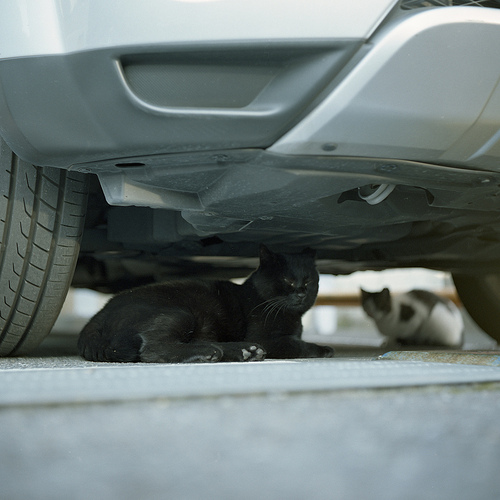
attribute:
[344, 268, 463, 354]
cat — white, brown, sitting down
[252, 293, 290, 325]
whiskers — white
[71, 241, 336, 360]
cat — black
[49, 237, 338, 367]
cat — black, sitting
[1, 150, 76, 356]
tire — car tire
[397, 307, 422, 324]
spots — dark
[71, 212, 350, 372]
cat — black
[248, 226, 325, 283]
ears — black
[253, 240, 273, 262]
ear — dark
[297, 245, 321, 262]
ear — dark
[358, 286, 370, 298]
ear — dark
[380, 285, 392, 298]
ear — dark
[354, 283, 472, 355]
cat — brown, white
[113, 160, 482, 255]
undercarriage — grey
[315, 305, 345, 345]
bucket — white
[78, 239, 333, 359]
black cat — sitting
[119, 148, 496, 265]
bottom — bottom part of car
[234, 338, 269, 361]
paw — cat's paw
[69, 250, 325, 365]
cat — black, under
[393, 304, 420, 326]
spots — grey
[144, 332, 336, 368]
legs — hind legs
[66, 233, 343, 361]
cat — black cat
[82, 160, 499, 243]
underside — of a car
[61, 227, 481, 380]
cats — under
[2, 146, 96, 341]
wheel — car wheel, brown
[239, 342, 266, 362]
paw — cat's paw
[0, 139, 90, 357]
tire — black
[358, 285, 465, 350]
cat — grey, white , blurry black , blurry black and white 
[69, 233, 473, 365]
cats — under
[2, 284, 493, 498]
pavement — light grey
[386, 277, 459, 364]
back — white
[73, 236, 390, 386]
hair — black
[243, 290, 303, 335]
whiskers — white 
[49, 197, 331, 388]
cat — black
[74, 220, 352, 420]
cat — black